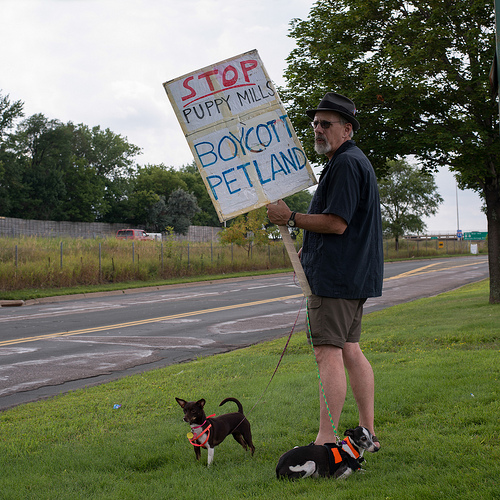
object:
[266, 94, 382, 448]
man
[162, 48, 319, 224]
sign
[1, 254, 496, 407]
road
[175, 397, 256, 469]
chihuahua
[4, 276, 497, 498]
grass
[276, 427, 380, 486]
dog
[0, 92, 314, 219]
trees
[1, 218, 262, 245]
fence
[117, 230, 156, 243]
truck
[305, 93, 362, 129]
hat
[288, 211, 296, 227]
wristwatch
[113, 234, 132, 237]
cover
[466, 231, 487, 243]
road sign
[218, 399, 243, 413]
puppy's tail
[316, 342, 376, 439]
legs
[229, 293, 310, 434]
leash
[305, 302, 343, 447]
leash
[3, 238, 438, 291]
field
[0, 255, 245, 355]
yellow strip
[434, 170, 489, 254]
background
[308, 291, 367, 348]
shorts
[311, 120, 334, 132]
glasses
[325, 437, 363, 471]
harness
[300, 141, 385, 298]
shirt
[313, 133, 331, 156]
facial hair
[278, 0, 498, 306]
tree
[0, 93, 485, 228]
background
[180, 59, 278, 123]
stop puppy mills